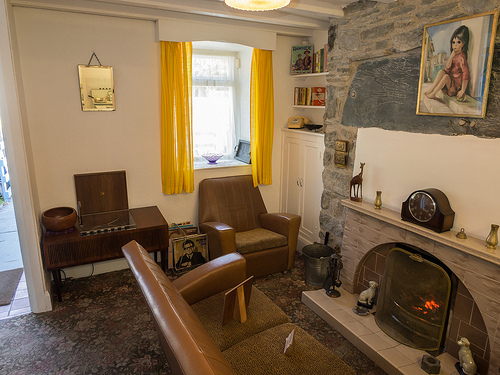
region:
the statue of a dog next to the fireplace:
[357, 279, 379, 306]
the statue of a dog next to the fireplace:
[456, 335, 475, 373]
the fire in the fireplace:
[410, 290, 442, 316]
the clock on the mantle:
[399, 188, 455, 232]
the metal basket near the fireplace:
[300, 242, 334, 284]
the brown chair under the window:
[198, 175, 302, 277]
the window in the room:
[154, 17, 274, 194]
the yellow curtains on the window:
[158, 42, 273, 195]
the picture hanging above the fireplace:
[415, 7, 499, 118]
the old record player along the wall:
[41, 170, 169, 299]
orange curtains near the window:
[157, 45, 272, 196]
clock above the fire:
[400, 186, 453, 231]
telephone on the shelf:
[285, 113, 307, 128]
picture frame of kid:
[413, 10, 495, 117]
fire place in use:
[366, 250, 452, 347]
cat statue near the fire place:
[355, 277, 377, 313]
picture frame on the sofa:
[220, 272, 257, 327]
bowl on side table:
[38, 205, 74, 231]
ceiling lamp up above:
[222, 0, 290, 13]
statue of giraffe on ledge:
[347, 160, 366, 202]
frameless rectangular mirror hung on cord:
[77, 50, 117, 112]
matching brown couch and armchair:
[122, 173, 352, 374]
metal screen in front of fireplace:
[370, 244, 457, 356]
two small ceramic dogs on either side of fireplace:
[352, 243, 487, 374]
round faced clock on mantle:
[389, 186, 456, 246]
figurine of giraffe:
[345, 158, 366, 202]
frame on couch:
[173, 271, 260, 351]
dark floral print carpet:
[0, 254, 379, 374]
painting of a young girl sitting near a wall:
[415, 11, 494, 116]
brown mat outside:
[0, 264, 26, 318]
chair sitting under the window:
[186, 160, 307, 281]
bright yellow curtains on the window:
[158, 44, 283, 209]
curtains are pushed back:
[160, 35, 275, 190]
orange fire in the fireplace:
[350, 246, 471, 352]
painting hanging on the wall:
[410, 9, 496, 122]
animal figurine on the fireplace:
[351, 276, 378, 311]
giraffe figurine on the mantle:
[344, 160, 366, 200]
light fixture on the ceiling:
[222, 0, 299, 12]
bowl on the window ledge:
[203, 150, 223, 166]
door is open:
[0, 110, 33, 326]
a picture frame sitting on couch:
[222, 274, 254, 327]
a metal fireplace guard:
[379, 243, 452, 355]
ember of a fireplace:
[416, 295, 438, 314]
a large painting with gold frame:
[414, 13, 496, 117]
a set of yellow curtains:
[159, 38, 272, 195]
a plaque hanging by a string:
[79, 50, 114, 110]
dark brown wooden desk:
[42, 200, 164, 306]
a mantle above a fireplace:
[338, 187, 494, 372]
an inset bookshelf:
[280, 25, 340, 133]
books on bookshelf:
[287, 47, 328, 112]